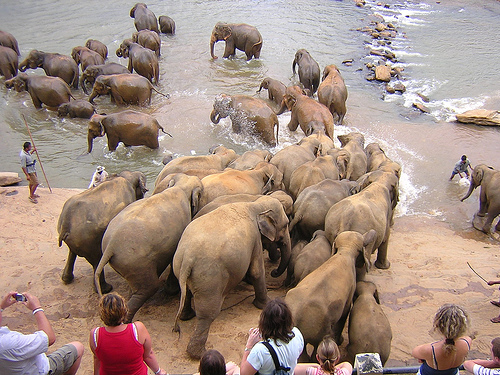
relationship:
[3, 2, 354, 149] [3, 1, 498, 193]
elephants in water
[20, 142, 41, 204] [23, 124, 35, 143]
man holding stick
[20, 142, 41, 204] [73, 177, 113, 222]
man near elephant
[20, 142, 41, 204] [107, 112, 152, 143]
man near elephant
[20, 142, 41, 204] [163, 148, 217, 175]
man near elephant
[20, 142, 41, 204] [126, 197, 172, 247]
man near elephant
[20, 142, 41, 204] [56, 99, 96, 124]
man near elephant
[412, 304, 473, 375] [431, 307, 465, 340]
woman has hair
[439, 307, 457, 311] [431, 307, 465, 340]
band in hair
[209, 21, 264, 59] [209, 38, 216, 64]
elephant has trunk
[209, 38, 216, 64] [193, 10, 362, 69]
trunk in water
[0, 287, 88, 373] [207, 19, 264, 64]
man taking picture of elephant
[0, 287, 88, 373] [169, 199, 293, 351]
man taking picture of elephant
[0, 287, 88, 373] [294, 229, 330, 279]
man taking picture of elephant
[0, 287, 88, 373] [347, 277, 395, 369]
man taking picture of elephant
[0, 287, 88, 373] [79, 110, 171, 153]
man taking picture of elephant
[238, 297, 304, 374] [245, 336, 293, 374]
woman carrying bag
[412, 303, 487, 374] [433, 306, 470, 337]
woman has hair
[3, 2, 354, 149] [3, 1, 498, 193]
elephants on water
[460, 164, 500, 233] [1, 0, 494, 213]
elephants walking towards water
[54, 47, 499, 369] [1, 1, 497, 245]
elephants walking towards water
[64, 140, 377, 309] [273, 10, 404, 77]
elephants walking towards water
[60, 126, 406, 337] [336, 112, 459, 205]
elephants walking in water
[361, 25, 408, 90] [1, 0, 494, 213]
big rocks in water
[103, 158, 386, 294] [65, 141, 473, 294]
elephants are together in a group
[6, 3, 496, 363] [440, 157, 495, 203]
elephant on water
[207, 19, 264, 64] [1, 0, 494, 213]
elephant standing in water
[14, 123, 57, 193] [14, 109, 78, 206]
man standing holding a stick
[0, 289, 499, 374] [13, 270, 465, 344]
crowd watching elephants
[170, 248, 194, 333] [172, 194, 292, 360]
elephant tail on elephant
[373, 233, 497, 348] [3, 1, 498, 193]
sand by water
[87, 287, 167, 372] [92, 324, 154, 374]
woman wearing a red shirt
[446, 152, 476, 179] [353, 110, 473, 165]
man in water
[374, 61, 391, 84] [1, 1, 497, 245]
rock are in water